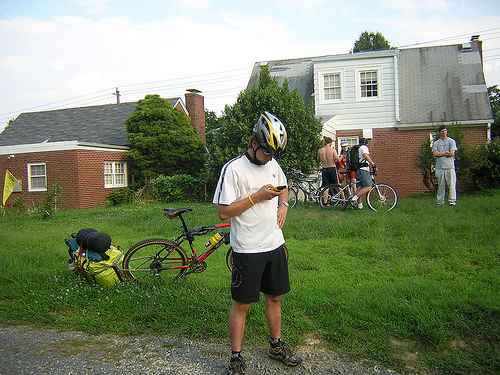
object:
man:
[212, 110, 306, 375]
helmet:
[252, 110, 288, 159]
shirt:
[211, 152, 289, 254]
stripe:
[208, 153, 246, 204]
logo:
[272, 173, 276, 177]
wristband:
[248, 195, 255, 206]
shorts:
[230, 243, 291, 305]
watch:
[277, 201, 290, 208]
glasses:
[262, 148, 275, 157]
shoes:
[267, 340, 303, 367]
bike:
[120, 206, 291, 288]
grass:
[307, 197, 499, 352]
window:
[353, 65, 384, 103]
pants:
[435, 167, 458, 203]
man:
[315, 137, 345, 207]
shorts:
[355, 167, 373, 190]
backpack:
[64, 227, 125, 288]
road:
[0, 323, 398, 374]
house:
[0, 88, 207, 213]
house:
[243, 33, 495, 202]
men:
[343, 137, 379, 211]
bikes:
[318, 164, 399, 213]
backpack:
[349, 144, 369, 172]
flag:
[2, 169, 20, 207]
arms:
[431, 142, 448, 157]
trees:
[122, 94, 211, 190]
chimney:
[184, 88, 208, 150]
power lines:
[120, 69, 254, 89]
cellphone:
[269, 185, 288, 193]